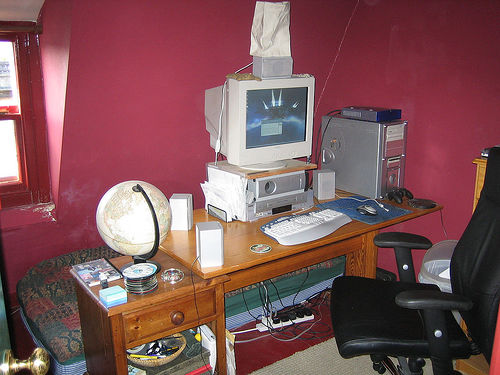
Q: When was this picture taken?
A: During the day.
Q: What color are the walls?
A: They are red.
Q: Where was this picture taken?
A: In front of a computer.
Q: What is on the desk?
A: A computer, keyboard, mouse, and speakers.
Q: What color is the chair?
A: Black.